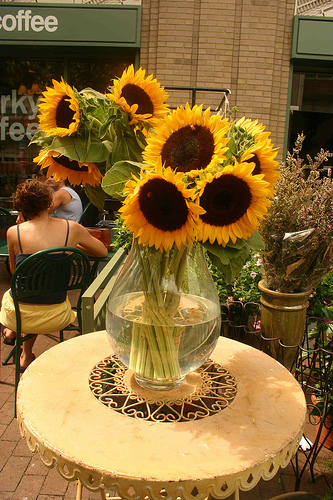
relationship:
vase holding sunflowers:
[104, 235, 219, 391] [28, 63, 280, 251]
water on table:
[107, 290, 222, 380] [19, 317, 299, 496]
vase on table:
[104, 235, 219, 391] [19, 317, 299, 496]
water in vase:
[104, 290, 221, 379] [105, 233, 221, 392]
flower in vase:
[36, 75, 81, 140] [105, 233, 221, 392]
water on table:
[107, 290, 222, 380] [6, 324, 314, 493]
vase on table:
[105, 233, 221, 392] [6, 324, 314, 493]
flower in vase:
[266, 137, 332, 279] [252, 278, 313, 368]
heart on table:
[149, 398, 183, 425] [19, 317, 299, 496]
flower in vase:
[257, 129, 333, 294] [258, 279, 312, 368]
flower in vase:
[238, 137, 281, 196] [105, 233, 221, 392]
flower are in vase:
[238, 137, 281, 196] [104, 235, 219, 391]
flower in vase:
[117, 159, 206, 252] [104, 235, 219, 391]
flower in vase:
[141, 99, 232, 184] [104, 235, 219, 391]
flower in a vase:
[106, 60, 170, 134] [104, 235, 219, 391]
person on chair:
[0, 177, 109, 373] [3, 243, 88, 364]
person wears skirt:
[0, 177, 109, 373] [0, 287, 76, 332]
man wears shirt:
[41, 160, 82, 222] [54, 185, 85, 221]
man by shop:
[41, 160, 82, 222] [2, 2, 142, 197]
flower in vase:
[190, 157, 274, 247] [104, 235, 219, 391]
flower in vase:
[107, 63, 170, 128] [104, 235, 219, 391]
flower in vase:
[224, 115, 271, 166] [104, 235, 219, 391]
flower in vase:
[35, 74, 80, 135] [104, 235, 219, 391]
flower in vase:
[30, 145, 105, 189] [104, 235, 219, 391]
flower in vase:
[118, 154, 207, 254] [104, 235, 219, 391]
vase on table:
[105, 233, 221, 392] [26, 288, 324, 474]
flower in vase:
[146, 99, 226, 185] [104, 235, 219, 391]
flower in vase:
[238, 137, 281, 196] [101, 216, 223, 395]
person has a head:
[3, 170, 109, 286] [6, 178, 66, 217]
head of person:
[6, 178, 66, 217] [3, 170, 109, 286]